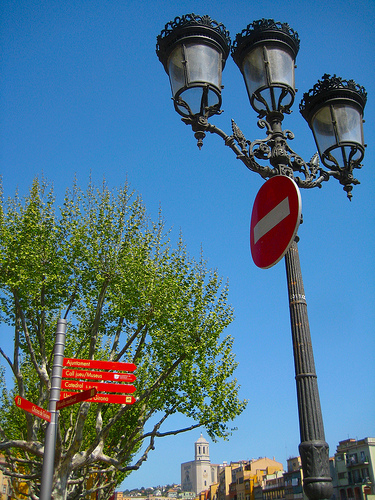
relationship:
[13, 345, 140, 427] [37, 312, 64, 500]
signs on pole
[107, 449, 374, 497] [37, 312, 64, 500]
buildings behind pole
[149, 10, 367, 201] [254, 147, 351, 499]
lights on post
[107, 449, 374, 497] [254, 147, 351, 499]
buildings behind post